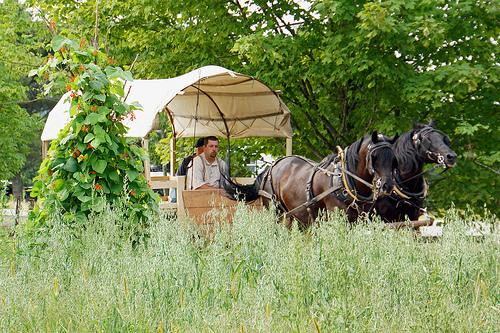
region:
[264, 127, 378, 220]
the horse is brown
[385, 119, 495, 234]
the horse is black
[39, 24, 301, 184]
the canopy is white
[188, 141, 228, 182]
man's shirt is white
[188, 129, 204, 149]
man is wearing a hat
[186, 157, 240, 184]
man is wearing suspenders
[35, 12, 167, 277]
red berries on plant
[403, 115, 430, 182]
horse has black hair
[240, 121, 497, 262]
horses are leading men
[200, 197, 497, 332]
grass is covering hooves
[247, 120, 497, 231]
The horses pull the wagon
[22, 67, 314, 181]
The wagon is covered on top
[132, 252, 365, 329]
The field is very tall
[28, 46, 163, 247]
The plant has red flowers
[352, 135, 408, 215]
The horse has a halter on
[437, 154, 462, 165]
The horse has a bit in its mouth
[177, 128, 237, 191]
A man sits in the front of the wagon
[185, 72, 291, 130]
Wood holds up the canopy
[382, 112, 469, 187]
The horse is looking forward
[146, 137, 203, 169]
People ride in the back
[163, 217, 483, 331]
the grass is tall and green.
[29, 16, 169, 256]
a small tree with leaves.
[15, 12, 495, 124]
a bunch of green trees.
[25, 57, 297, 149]
a beige wagon top.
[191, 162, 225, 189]
a man is wearing a white shirt.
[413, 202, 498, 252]
a white truck is parked in the forest.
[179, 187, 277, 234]
a brown bench.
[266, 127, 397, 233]
a beautiful brown horse.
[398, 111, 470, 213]
a huge black horse.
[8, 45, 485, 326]
a man is riding the horse wagon.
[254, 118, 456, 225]
two horses pulling a carriage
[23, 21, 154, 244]
tall green plant with orange flowers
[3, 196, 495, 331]
green shrubs growing in ground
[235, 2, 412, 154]
large green tree in the background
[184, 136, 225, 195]
man sitting in carriage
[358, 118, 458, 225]
black horse pulling carriage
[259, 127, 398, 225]
brown horse pulling carriage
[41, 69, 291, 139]
roof area of carriage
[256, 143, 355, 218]
harness around the horse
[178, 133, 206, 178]
man in black sitting in carriage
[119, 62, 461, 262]
two horses pulling a wagon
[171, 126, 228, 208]
two people sitting inside a wagon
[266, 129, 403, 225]
a black and brown horse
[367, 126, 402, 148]
two ears of the horse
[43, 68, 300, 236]
a wagon with two passengers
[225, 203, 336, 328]
tall bushes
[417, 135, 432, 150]
a blinder of a horse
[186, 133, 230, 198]
a man driving the wagon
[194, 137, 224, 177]
a guy wearing a suspender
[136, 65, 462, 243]
two horses attached to the wagon